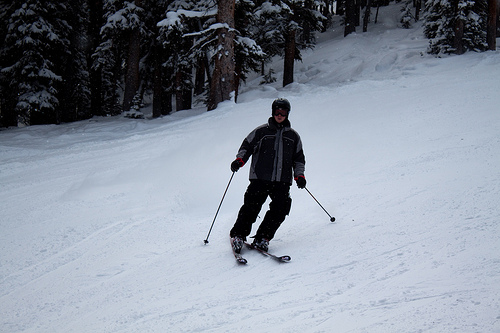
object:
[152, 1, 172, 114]
tree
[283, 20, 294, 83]
trunk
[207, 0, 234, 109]
tree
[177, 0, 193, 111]
tree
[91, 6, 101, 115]
trunk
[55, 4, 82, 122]
tree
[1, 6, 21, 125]
tree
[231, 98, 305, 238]
person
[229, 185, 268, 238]
leg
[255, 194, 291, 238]
leg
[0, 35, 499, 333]
snow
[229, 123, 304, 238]
snow suit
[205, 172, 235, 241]
pole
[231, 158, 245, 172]
hand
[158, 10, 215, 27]
snow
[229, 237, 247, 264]
ski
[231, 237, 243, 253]
foot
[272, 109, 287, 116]
googles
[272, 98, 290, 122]
head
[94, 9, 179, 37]
leaves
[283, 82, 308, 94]
pile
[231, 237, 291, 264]
pair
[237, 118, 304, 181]
jacket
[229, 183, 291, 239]
pants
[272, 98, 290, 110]
helmet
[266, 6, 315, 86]
trees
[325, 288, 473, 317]
tracks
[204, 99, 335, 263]
skating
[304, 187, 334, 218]
stick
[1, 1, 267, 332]
left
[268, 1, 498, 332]
right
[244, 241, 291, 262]
ski